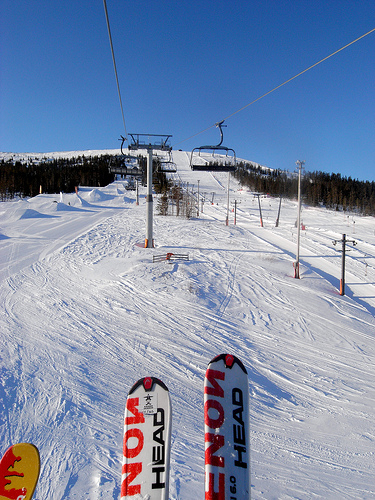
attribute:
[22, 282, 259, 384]
tracks — SKIING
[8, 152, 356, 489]
slope — SNOWY, SNOW COVERED, SKIING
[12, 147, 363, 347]
hill — SNOW COVERED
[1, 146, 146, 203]
trees — DENSELY GROWING, LARGE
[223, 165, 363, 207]
trees — FOREST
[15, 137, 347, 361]
slope — SKIING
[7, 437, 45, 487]
ski — YELLOW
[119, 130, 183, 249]
support — TALL, SKI LIFT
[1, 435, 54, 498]
ski — RED, YELLOW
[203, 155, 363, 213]
trees — GREEN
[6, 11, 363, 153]
sky — CLEAR, BLUE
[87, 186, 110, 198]
hill — SMALL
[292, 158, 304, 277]
pole — metallic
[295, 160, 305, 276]
pole — silver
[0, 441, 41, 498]
ski — yellow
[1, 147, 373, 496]
snow — white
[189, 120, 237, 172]
ski lift — distant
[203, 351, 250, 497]
ski — white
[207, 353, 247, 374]
tip — black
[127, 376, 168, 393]
tip — black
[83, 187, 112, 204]
ramp — snow, distant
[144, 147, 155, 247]
pole — tall, large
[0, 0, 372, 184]
sky — clear, blue, large